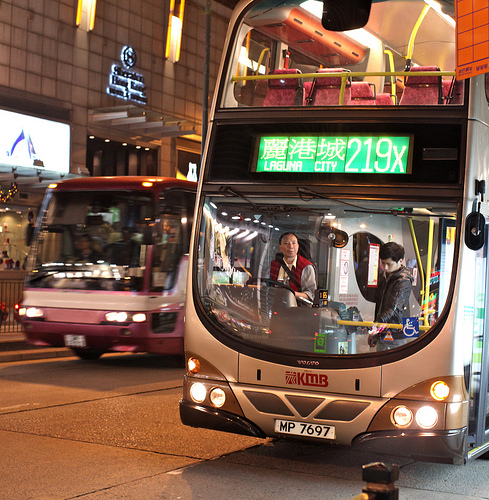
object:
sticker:
[393, 310, 424, 340]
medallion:
[297, 352, 326, 368]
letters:
[315, 371, 328, 391]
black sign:
[105, 43, 152, 111]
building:
[0, 0, 234, 309]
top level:
[200, 0, 488, 124]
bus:
[15, 171, 215, 367]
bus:
[174, 0, 488, 469]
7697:
[296, 422, 330, 438]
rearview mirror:
[462, 175, 486, 264]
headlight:
[386, 400, 414, 433]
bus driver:
[257, 222, 319, 316]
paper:
[365, 242, 380, 289]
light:
[412, 403, 442, 432]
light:
[425, 378, 455, 402]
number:
[294, 418, 308, 440]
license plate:
[271, 419, 340, 440]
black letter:
[277, 415, 289, 436]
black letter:
[285, 417, 294, 435]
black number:
[306, 422, 313, 436]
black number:
[311, 420, 320, 437]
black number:
[322, 424, 331, 435]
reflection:
[198, 198, 273, 342]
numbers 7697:
[297, 421, 332, 440]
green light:
[253, 128, 417, 176]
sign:
[253, 129, 413, 180]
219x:
[341, 128, 408, 181]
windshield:
[190, 191, 463, 357]